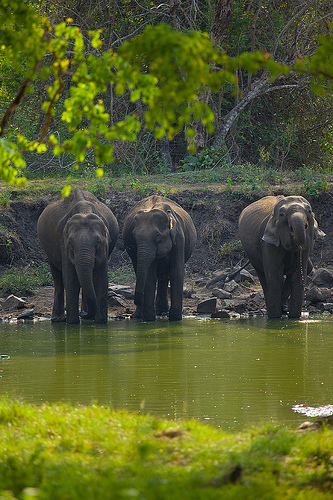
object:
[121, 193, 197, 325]
elephant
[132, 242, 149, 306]
trunk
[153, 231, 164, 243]
eye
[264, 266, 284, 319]
leg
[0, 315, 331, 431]
water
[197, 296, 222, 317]
rock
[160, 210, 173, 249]
ear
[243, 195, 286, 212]
back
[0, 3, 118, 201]
tree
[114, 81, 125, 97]
leaves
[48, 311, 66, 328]
foot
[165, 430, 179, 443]
mud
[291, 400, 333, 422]
ripples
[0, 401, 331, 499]
grass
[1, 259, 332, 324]
shore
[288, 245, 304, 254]
mouth